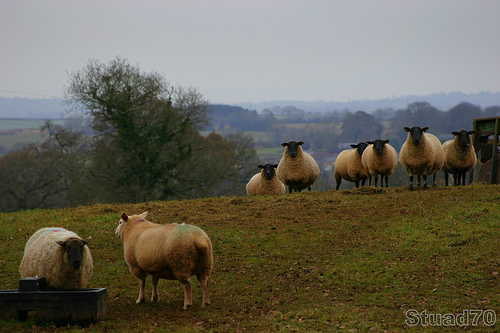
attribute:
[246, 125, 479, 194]
herd — sheep, outdoor, grazing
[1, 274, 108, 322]
water trough — for sheep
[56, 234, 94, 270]
face — black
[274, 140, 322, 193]
sheep — wooly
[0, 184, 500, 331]
hill — brown, green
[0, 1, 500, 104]
sky — gray, hazy, overcast, cloudy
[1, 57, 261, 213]
trees — large, green, nearby, bare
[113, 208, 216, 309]
sheep — white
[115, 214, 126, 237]
face — white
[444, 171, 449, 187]
leg — skinny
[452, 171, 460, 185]
leg — skinny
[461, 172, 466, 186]
leg — skinny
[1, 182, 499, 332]
grass — brown, green, patchy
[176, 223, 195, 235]
mark — green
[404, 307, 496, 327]
text — white, photographer name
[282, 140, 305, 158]
face — black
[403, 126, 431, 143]
face — black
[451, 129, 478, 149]
face — black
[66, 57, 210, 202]
tree — green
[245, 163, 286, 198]
sheep — wooly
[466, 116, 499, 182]
sign — brown, wooden